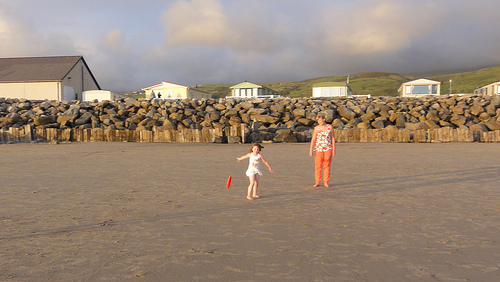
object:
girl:
[237, 142, 274, 202]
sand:
[1, 146, 498, 280]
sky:
[1, 0, 499, 52]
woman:
[308, 115, 337, 188]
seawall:
[2, 94, 498, 144]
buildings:
[226, 80, 282, 98]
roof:
[0, 55, 104, 89]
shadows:
[329, 165, 498, 199]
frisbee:
[225, 176, 233, 189]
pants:
[313, 149, 331, 185]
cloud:
[162, 3, 282, 51]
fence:
[1, 125, 498, 141]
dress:
[246, 153, 264, 178]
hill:
[126, 64, 499, 96]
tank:
[314, 125, 335, 152]